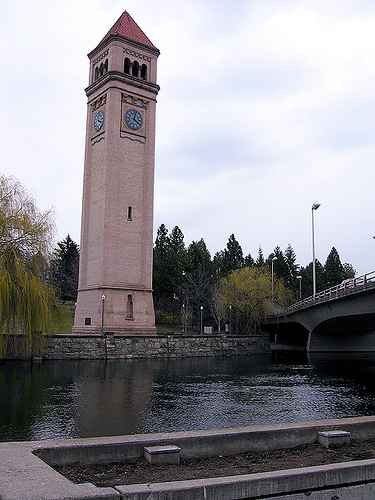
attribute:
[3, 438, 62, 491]
wall — stone 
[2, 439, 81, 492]
wall — cement 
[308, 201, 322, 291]
light — street 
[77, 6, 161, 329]
tower — four-sided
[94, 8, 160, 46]
roof — pointed 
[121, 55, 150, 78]
arches — three 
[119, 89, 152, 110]
decorations — row of stone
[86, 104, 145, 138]
clock — afternoon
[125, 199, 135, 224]
opening — short narrow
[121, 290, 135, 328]
lipstick — tower, opening resembling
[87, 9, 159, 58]
roof — clay, red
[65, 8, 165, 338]
tower — on the bank of a river, body , stone 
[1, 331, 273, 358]
wall — stone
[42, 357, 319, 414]
stream — of water, below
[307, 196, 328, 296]
street light — up above near the road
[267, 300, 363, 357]
bridge — to the side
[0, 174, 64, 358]
green tree — in the foreground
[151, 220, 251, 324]
green trees — in the background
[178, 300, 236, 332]
more lampposts — in the background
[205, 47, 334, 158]
cloudy sky — up above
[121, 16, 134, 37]
red roof — of the tower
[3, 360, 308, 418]
murky water — under the bridge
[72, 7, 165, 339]
tall/clock — tower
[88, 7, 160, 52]
roof — of the clock tower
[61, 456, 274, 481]
dirt — in the foreground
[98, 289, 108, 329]
light post — in front of the clock tower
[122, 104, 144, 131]
clock — on the front of the clock tower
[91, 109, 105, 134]
clock — on the side of the clock tower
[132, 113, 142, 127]
clock hands — on front clock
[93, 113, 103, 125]
clock hands — on side clock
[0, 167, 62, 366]
partial tree — hanging over the water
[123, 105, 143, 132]
clock — on a tower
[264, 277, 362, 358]
bridge — over a river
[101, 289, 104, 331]
lamp post — black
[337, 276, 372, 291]
car — red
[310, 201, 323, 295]
lamp post — white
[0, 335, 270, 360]
wall — gray, stone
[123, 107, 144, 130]
clock — on the tower